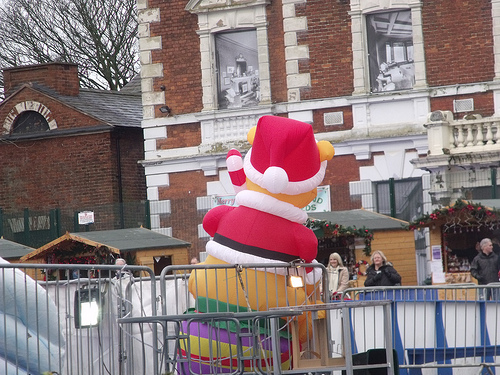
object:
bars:
[389, 177, 397, 218]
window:
[372, 175, 426, 224]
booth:
[399, 196, 499, 301]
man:
[469, 237, 499, 301]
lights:
[453, 228, 457, 234]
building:
[0, 60, 152, 250]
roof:
[0, 69, 143, 128]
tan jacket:
[321, 265, 354, 293]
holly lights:
[456, 212, 463, 233]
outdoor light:
[286, 274, 304, 289]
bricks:
[164, 20, 173, 24]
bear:
[184, 114, 335, 346]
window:
[212, 26, 263, 112]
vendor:
[468, 239, 482, 265]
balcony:
[408, 108, 500, 171]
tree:
[0, 0, 142, 102]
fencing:
[0, 257, 500, 375]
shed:
[300, 208, 419, 301]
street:
[0, 195, 500, 374]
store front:
[400, 197, 500, 300]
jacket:
[363, 261, 402, 287]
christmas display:
[172, 114, 337, 373]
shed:
[399, 198, 499, 303]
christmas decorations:
[400, 187, 499, 233]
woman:
[361, 249, 402, 288]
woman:
[319, 252, 350, 303]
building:
[133, 0, 498, 302]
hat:
[242, 115, 328, 197]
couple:
[319, 249, 402, 300]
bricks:
[88, 185, 101, 189]